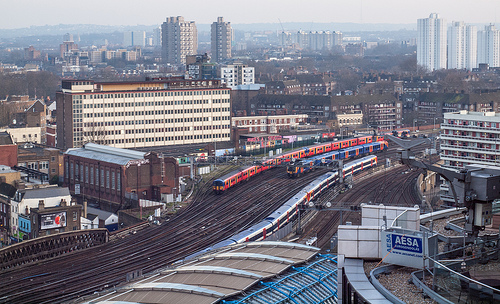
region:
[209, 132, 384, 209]
Trains on railroad tracks.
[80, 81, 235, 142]
Large building with many windows.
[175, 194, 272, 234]
Many railroad tracks.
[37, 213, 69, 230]
An advertisement sign on building.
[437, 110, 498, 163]
A large building with balconies.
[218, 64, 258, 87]
Twin building located in city.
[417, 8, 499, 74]
Several High-rise building in city.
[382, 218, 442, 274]
AESA billboard sign near railroad tracks.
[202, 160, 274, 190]
Red train on railroad tracks.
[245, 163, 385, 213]
Silver train on railroad tracks.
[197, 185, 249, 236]
railroad tracks in city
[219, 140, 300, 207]
red and blue train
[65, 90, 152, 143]
industrial building in distance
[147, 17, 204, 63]
apartment complex in distance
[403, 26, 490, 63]
ensemble of white apartments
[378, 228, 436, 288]
AESA advertisement sign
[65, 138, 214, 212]
factory plant of some sort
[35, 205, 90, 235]
random billboard ad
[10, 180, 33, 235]
random white apartment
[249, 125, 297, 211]
red and blue train on tracks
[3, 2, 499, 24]
the grey sky above everything in the town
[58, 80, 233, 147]
a large building next to the tracks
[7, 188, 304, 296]
the empty section of the train tracks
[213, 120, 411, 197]
a couple of long trains on the track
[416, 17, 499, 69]
a cluster of tall building off to the side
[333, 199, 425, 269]
some signs sitting on top of the building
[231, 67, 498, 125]
so many buildings next to each other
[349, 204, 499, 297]
the roof of the building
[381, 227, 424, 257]
a name on the sign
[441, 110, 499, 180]
another tall building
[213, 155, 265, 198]
red and blue train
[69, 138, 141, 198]
factory building thats brown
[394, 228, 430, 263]
aesa ad on right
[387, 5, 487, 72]
white apartment buildings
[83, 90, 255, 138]
apartment complex by tracks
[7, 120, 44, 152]
apartment complex thats white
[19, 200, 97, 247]
red and blue billboard by tracks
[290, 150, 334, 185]
second red and blue train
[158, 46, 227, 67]
brown high rise apartment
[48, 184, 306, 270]
Train tracks at a station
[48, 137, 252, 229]
Building by train tracks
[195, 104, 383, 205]
Red train on tracks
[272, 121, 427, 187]
Blue and orange train on tracks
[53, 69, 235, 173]
Gray and white building in a city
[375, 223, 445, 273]
White and blue sign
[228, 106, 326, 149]
Brown and white building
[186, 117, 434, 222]
Two trains on tracks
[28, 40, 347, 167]
Buildings in a city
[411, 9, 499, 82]
Three white tall buildings